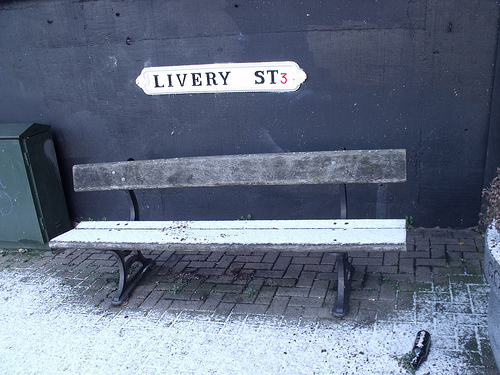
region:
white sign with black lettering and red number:
[125, 55, 315, 92]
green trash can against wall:
[2, 123, 62, 249]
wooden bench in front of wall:
[47, 150, 412, 315]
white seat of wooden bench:
[57, 215, 403, 262]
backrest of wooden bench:
[68, 147, 405, 189]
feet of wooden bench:
[102, 248, 365, 319]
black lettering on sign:
[150, 69, 279, 84]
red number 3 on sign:
[280, 73, 288, 87]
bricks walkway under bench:
[0, 219, 479, 320]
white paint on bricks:
[2, 281, 477, 372]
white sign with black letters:
[128, 50, 306, 108]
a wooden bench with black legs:
[58, 146, 438, 332]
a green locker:
[2, 113, 72, 258]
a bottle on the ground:
[392, 324, 443, 374]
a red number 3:
[276, 68, 288, 87]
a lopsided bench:
[53, 148, 440, 332]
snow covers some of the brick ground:
[13, 280, 458, 372]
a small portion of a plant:
[464, 160, 499, 251]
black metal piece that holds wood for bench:
[102, 160, 162, 308]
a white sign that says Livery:
[126, 51, 306, 109]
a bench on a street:
[42, 141, 416, 326]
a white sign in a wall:
[127, 58, 315, 100]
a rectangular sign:
[128, 58, 311, 98]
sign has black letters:
[127, 55, 311, 98]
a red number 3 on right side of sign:
[129, 56, 313, 96]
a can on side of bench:
[403, 321, 440, 371]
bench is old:
[46, 146, 423, 318]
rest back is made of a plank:
[65, 148, 417, 197]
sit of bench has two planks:
[41, 214, 413, 257]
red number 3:
[270, 60, 300, 89]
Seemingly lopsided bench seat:
[47, 146, 412, 317]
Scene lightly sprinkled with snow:
[1, 202, 498, 374]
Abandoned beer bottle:
[388, 325, 440, 373]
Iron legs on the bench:
[97, 245, 365, 324]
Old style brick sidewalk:
[1, 233, 496, 372]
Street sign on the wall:
[127, 58, 315, 103]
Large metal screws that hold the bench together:
[110, 163, 129, 186]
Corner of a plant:
[475, 153, 498, 252]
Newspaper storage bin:
[0, 113, 75, 255]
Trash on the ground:
[147, 266, 230, 309]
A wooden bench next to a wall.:
[45, 120, 428, 318]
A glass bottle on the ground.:
[400, 323, 440, 370]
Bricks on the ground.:
[156, 270, 302, 307]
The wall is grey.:
[30, 8, 391, 53]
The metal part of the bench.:
[321, 255, 363, 317]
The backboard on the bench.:
[65, 140, 411, 195]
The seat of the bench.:
[48, 205, 410, 257]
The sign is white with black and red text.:
[128, 55, 319, 95]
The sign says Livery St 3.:
[142, 63, 297, 88]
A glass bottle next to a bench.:
[50, 144, 456, 370]